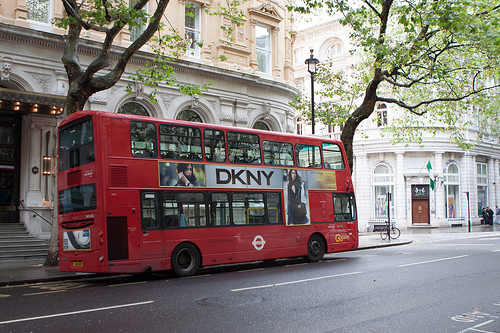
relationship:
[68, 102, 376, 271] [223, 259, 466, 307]
bus on road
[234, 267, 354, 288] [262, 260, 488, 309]
line on road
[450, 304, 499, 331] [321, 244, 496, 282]
writing on road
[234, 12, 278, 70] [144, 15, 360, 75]
window on building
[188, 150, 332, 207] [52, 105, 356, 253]
sign besides bus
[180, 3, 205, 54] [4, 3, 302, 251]
window on building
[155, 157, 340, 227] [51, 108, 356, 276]
sign on bus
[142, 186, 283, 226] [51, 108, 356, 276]
window on bus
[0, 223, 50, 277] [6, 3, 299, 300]
stairs in front of building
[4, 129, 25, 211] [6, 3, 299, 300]
door on building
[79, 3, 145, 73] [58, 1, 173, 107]
limb of tree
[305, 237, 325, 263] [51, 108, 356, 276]
wheel on bus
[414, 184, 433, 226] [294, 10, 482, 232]
door to building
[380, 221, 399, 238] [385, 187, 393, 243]
bicycle leaning on sign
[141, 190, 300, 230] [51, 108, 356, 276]
window on bus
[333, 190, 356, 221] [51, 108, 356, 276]
window on bus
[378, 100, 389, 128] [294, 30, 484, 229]
window in building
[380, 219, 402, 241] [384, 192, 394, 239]
bicycle on pole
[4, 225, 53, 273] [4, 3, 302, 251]
steps going into building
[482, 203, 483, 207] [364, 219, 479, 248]
people standing on street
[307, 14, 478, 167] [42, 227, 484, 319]
tree hanging over street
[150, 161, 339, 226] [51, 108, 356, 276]
advertisement on side of bus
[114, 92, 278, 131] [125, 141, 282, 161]
arches over windows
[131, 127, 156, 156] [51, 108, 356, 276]
window on bus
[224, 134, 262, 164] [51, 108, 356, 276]
window on bus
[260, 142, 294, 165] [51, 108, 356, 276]
window on bus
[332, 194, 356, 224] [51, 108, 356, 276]
window on bus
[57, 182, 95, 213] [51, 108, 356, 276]
window on bus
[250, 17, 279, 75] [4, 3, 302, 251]
window on building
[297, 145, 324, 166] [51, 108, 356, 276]
window on a bus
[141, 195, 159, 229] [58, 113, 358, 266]
glass window on bus